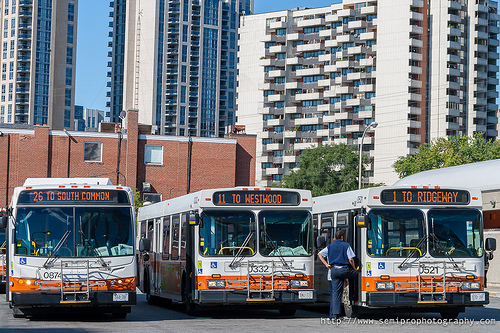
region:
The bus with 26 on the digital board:
[0, 173, 143, 322]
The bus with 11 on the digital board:
[133, 181, 321, 311]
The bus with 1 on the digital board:
[313, 181, 492, 311]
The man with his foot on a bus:
[316, 227, 361, 322]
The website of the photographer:
[316, 313, 498, 331]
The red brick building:
[0, 105, 264, 220]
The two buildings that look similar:
[0, 0, 255, 135]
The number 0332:
[245, 261, 276, 276]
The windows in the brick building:
[76, 135, 166, 169]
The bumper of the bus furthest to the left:
[6, 289, 140, 307]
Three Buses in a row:
[10, 170, 480, 319]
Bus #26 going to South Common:
[7, 176, 150, 316]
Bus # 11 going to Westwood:
[140, 180, 317, 315]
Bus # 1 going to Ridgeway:
[317, 185, 484, 318]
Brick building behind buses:
[1, 117, 271, 219]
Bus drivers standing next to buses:
[317, 225, 367, 325]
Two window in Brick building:
[76, 135, 175, 170]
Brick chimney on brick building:
[122, 104, 142, 196]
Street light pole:
[348, 116, 385, 191]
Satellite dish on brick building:
[113, 105, 127, 121]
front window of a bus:
[261, 219, 287, 256]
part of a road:
[281, 315, 305, 330]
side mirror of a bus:
[136, 237, 153, 255]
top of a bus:
[220, 178, 310, 195]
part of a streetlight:
[361, 111, 379, 137]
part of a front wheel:
[178, 282, 185, 307]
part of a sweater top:
[321, 238, 343, 257]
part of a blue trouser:
[334, 287, 343, 314]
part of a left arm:
[316, 257, 328, 266]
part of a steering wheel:
[93, 225, 117, 240]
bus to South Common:
[6, 175, 143, 322]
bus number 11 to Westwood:
[138, 184, 315, 314]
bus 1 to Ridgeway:
[313, 182, 496, 319]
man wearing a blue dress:
[318, 229, 365, 324]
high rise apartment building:
[236, 0, 499, 188]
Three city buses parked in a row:
[1, 167, 497, 331]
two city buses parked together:
[136, 178, 498, 325]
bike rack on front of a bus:
[50, 245, 105, 315]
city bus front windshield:
[10, 196, 138, 261]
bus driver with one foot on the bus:
[314, 182, 492, 326]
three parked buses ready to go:
[7, 171, 492, 316]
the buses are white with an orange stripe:
[5, 165, 486, 316]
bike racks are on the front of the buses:
[15, 250, 486, 305]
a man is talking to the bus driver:
[315, 220, 462, 321]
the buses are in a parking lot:
[2, 171, 497, 316]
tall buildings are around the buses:
[9, 4, 498, 315]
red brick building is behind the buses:
[2, 103, 257, 219]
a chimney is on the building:
[120, 105, 140, 202]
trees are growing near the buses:
[282, 131, 493, 321]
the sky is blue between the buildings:
[21, 5, 493, 160]